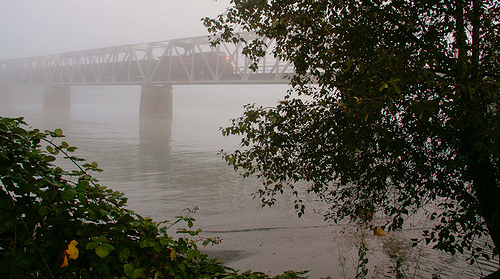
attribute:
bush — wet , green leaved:
[3, 117, 228, 275]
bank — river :
[211, 219, 307, 251]